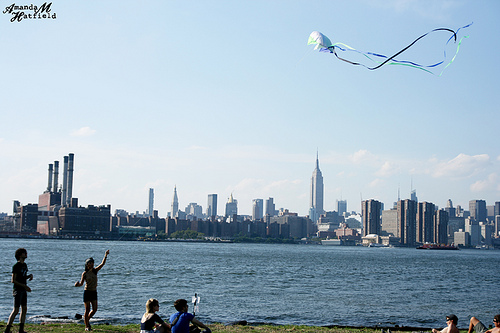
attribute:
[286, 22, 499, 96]
kite — in sky, blowing, white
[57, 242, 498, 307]
ocean — blue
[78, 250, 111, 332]
woman — pointing, in park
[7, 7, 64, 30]
photographer — amanda m hatfield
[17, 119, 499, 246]
buildings — in city, tall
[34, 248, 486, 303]
water — blue, rippled, oceanic, seawater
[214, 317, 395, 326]
grass — green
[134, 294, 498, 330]
people — sitting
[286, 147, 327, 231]
building — skyscraper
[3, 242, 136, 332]
people — running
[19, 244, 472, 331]
park — green